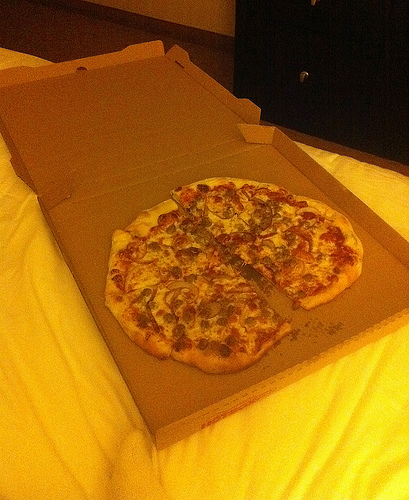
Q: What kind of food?
A: Pizza.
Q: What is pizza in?
A: Box.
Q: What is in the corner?
A: Furniture.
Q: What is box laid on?
A: Bed.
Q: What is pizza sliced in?
A: Half.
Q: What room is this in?
A: Bedroom.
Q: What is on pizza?
A: Pepperoni.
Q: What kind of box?
A: Cardboard.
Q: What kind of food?
A: Pizza.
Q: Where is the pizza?
A: Box.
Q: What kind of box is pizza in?
A: Cardboard.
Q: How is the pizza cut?
A: Half.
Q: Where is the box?
A: Bed.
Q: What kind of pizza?
A: Combo.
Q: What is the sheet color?
A: Yellow.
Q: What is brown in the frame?
A: The crust on the pizza.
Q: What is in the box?
A: A slice of pizza.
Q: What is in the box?
A: A slice of pizza.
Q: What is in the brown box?
A: A slice of pizza.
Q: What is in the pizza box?
A: A slice of pizza?.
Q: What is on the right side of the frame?
A: A slice of pizza.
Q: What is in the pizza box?
A: A pizza pie.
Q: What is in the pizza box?
A: A whole pizza.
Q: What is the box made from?
A: The box is made from cardboard.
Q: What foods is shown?
A: Pizza.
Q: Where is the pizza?
A: In the box.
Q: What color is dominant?
A: Yellow.